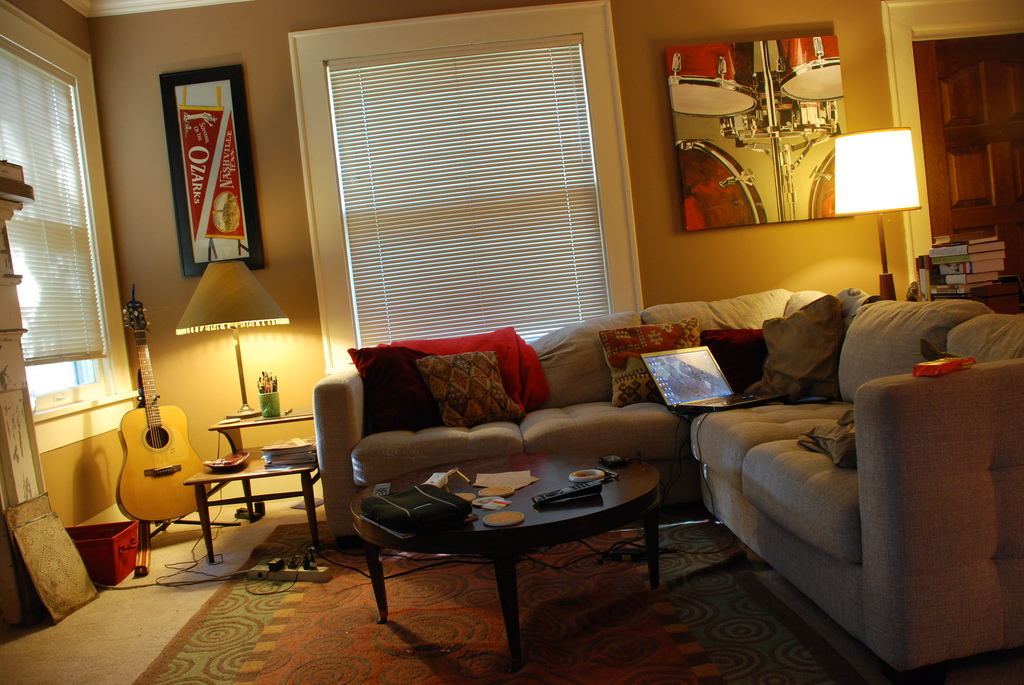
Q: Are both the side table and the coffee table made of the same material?
A: Yes, both the side table and the coffee table are made of wood.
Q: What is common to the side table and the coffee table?
A: The material, both the side table and the coffee table are wooden.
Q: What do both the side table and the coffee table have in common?
A: The material, both the side table and the coffee table are wooden.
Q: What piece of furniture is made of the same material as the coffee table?
A: The side table is made of the same material as the coffee table.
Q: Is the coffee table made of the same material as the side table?
A: Yes, both the coffee table and the side table are made of wood.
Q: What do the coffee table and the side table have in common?
A: The material, both the coffee table and the side table are wooden.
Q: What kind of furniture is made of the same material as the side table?
A: The coffee table is made of the same material as the side table.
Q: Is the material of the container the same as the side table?
A: No, the container is made of plastic and the side table is made of wood.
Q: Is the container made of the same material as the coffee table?
A: No, the container is made of plastic and the coffee table is made of wood.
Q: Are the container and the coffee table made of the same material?
A: No, the container is made of plastic and the coffee table is made of wood.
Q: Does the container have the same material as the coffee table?
A: No, the container is made of plastic and the coffee table is made of wood.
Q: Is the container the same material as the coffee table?
A: No, the container is made of plastic and the coffee table is made of wood.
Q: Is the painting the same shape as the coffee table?
A: No, the coffee table is round and the painting is square.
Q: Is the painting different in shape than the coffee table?
A: Yes, the coffee table is round and the painting is square.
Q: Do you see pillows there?
A: Yes, there are pillows.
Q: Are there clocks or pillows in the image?
A: Yes, there are pillows.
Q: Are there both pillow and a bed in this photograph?
A: No, there are pillows but no beds.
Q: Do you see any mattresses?
A: No, there are no mattresses.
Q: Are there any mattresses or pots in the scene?
A: No, there are no mattresses or pots.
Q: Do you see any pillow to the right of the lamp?
A: Yes, there are pillows to the right of the lamp.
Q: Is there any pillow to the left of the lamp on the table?
A: No, the pillows are to the right of the lamp.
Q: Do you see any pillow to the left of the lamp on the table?
A: No, the pillows are to the right of the lamp.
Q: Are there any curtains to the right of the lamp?
A: No, there are pillows to the right of the lamp.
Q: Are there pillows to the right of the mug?
A: Yes, there are pillows to the right of the mug.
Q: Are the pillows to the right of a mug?
A: Yes, the pillows are to the right of a mug.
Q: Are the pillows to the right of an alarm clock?
A: No, the pillows are to the right of a mug.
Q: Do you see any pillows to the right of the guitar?
A: Yes, there are pillows to the right of the guitar.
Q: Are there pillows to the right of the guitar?
A: Yes, there are pillows to the right of the guitar.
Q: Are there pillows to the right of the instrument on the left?
A: Yes, there are pillows to the right of the guitar.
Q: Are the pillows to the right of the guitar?
A: Yes, the pillows are to the right of the guitar.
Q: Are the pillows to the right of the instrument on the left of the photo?
A: Yes, the pillows are to the right of the guitar.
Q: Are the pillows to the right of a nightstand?
A: No, the pillows are to the right of the guitar.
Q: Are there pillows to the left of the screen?
A: Yes, there are pillows to the left of the screen.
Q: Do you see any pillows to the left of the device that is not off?
A: Yes, there are pillows to the left of the screen.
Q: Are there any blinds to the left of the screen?
A: No, there are pillows to the left of the screen.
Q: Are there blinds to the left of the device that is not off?
A: No, there are pillows to the left of the screen.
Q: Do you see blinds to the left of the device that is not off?
A: No, there are pillows to the left of the screen.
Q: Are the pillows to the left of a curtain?
A: No, the pillows are to the left of the screen.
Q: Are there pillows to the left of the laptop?
A: Yes, there are pillows to the left of the laptop.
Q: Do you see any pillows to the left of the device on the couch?
A: Yes, there are pillows to the left of the laptop.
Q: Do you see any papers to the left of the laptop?
A: No, there are pillows to the left of the laptop.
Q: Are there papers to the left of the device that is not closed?
A: No, there are pillows to the left of the laptop.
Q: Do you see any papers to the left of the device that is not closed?
A: No, there are pillows to the left of the laptop.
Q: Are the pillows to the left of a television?
A: No, the pillows are to the left of the laptop computer.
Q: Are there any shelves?
A: No, there are no shelves.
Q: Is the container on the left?
A: Yes, the container is on the left of the image.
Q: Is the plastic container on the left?
A: Yes, the container is on the left of the image.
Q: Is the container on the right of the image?
A: No, the container is on the left of the image.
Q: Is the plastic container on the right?
A: No, the container is on the left of the image.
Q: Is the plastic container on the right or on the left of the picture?
A: The container is on the left of the image.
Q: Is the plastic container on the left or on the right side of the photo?
A: The container is on the left of the image.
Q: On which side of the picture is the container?
A: The container is on the left of the image.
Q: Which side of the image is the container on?
A: The container is on the left of the image.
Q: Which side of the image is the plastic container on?
A: The container is on the left of the image.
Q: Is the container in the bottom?
A: Yes, the container is in the bottom of the image.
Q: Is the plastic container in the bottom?
A: Yes, the container is in the bottom of the image.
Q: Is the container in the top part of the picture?
A: No, the container is in the bottom of the image.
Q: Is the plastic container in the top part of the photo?
A: No, the container is in the bottom of the image.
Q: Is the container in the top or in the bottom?
A: The container is in the bottom of the image.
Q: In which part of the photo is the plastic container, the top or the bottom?
A: The container is in the bottom of the image.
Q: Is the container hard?
A: Yes, the container is hard.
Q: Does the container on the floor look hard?
A: Yes, the container is hard.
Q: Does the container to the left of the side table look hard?
A: Yes, the container is hard.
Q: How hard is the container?
A: The container is hard.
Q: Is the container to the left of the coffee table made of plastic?
A: Yes, the container is made of plastic.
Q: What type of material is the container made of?
A: The container is made of plastic.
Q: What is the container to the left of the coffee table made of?
A: The container is made of plastic.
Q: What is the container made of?
A: The container is made of plastic.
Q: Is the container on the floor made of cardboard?
A: No, the container is made of plastic.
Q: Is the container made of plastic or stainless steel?
A: The container is made of plastic.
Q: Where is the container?
A: The container is on the floor.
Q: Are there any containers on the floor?
A: Yes, there is a container on the floor.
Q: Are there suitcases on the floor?
A: No, there is a container on the floor.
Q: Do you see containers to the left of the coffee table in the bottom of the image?
A: Yes, there is a container to the left of the coffee table.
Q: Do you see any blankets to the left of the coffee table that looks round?
A: No, there is a container to the left of the coffee table.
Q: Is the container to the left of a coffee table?
A: Yes, the container is to the left of a coffee table.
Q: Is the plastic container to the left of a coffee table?
A: Yes, the container is to the left of a coffee table.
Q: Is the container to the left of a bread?
A: No, the container is to the left of a coffee table.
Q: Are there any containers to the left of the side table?
A: Yes, there is a container to the left of the side table.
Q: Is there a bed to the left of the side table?
A: No, there is a container to the left of the side table.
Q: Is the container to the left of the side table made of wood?
A: Yes, the container is to the left of the side table.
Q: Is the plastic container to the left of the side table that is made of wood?
A: Yes, the container is to the left of the side table.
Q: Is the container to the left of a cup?
A: No, the container is to the left of the side table.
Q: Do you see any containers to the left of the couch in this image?
A: Yes, there is a container to the left of the couch.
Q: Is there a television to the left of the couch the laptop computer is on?
A: No, there is a container to the left of the couch.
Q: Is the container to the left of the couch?
A: Yes, the container is to the left of the couch.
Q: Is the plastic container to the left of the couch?
A: Yes, the container is to the left of the couch.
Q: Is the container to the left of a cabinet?
A: No, the container is to the left of the couch.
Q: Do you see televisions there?
A: No, there are no televisions.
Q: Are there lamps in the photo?
A: Yes, there is a lamp.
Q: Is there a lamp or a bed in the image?
A: Yes, there is a lamp.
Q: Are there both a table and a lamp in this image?
A: Yes, there are both a lamp and a table.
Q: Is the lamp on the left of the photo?
A: Yes, the lamp is on the left of the image.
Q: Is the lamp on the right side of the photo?
A: No, the lamp is on the left of the image.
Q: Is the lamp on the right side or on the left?
A: The lamp is on the left of the image.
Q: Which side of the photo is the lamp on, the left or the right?
A: The lamp is on the left of the image.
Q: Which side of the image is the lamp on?
A: The lamp is on the left of the image.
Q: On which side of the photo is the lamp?
A: The lamp is on the left of the image.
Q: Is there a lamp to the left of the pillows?
A: Yes, there is a lamp to the left of the pillows.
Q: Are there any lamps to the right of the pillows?
A: No, the lamp is to the left of the pillows.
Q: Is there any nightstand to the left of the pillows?
A: No, there is a lamp to the left of the pillows.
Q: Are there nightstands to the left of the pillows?
A: No, there is a lamp to the left of the pillows.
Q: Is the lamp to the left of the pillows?
A: Yes, the lamp is to the left of the pillows.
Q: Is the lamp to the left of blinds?
A: No, the lamp is to the left of the pillows.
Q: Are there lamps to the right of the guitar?
A: Yes, there is a lamp to the right of the guitar.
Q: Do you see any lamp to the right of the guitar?
A: Yes, there is a lamp to the right of the guitar.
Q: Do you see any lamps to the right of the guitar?
A: Yes, there is a lamp to the right of the guitar.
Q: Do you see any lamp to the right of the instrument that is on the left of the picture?
A: Yes, there is a lamp to the right of the guitar.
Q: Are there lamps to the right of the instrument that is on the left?
A: Yes, there is a lamp to the right of the guitar.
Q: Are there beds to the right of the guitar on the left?
A: No, there is a lamp to the right of the guitar.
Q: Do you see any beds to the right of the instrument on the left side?
A: No, there is a lamp to the right of the guitar.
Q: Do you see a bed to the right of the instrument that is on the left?
A: No, there is a lamp to the right of the guitar.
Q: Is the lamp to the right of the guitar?
A: Yes, the lamp is to the right of the guitar.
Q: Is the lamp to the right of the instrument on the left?
A: Yes, the lamp is to the right of the guitar.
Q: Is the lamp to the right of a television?
A: No, the lamp is to the right of the guitar.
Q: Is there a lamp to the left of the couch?
A: Yes, there is a lamp to the left of the couch.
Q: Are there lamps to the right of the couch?
A: No, the lamp is to the left of the couch.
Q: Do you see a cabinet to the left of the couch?
A: No, there is a lamp to the left of the couch.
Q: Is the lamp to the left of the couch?
A: Yes, the lamp is to the left of the couch.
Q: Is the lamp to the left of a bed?
A: No, the lamp is to the left of the couch.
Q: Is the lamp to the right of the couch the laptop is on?
A: No, the lamp is to the left of the couch.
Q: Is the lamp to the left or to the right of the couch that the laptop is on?
A: The lamp is to the left of the couch.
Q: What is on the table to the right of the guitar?
A: The lamp is on the table.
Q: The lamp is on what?
A: The lamp is on the table.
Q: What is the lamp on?
A: The lamp is on the table.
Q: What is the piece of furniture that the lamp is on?
A: The piece of furniture is a table.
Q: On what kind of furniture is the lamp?
A: The lamp is on the table.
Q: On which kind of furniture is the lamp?
A: The lamp is on the table.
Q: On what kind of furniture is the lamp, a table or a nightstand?
A: The lamp is on a table.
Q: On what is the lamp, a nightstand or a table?
A: The lamp is on a table.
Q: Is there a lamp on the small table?
A: Yes, there is a lamp on the table.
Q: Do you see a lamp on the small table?
A: Yes, there is a lamp on the table.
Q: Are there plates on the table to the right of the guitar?
A: No, there is a lamp on the table.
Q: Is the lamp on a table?
A: Yes, the lamp is on a table.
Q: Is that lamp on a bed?
A: No, the lamp is on a table.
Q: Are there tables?
A: Yes, there is a table.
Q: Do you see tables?
A: Yes, there is a table.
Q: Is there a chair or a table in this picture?
A: Yes, there is a table.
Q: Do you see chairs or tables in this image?
A: Yes, there is a table.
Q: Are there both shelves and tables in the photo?
A: No, there is a table but no shelves.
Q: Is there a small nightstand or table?
A: Yes, there is a small table.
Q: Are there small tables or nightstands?
A: Yes, there is a small table.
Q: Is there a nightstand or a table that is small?
A: Yes, the table is small.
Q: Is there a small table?
A: Yes, there is a small table.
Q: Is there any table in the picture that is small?
A: Yes, there is a table that is small.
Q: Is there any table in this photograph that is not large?
A: Yes, there is a small table.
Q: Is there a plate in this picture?
A: No, there are no plates.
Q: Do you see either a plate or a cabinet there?
A: No, there are no plates or cabinets.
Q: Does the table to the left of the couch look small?
A: Yes, the table is small.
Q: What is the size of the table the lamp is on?
A: The table is small.